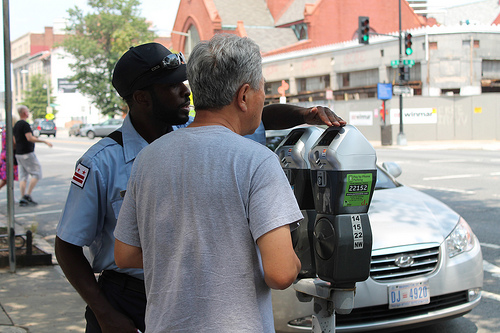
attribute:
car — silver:
[267, 128, 483, 331]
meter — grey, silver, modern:
[276, 125, 373, 290]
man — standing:
[115, 34, 302, 332]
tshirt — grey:
[114, 124, 299, 332]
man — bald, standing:
[13, 107, 52, 209]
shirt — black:
[13, 119, 36, 154]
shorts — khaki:
[16, 156, 44, 177]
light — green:
[362, 34, 368, 41]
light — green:
[405, 45, 411, 54]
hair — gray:
[186, 32, 263, 108]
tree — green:
[20, 78, 55, 131]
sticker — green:
[342, 173, 373, 212]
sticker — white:
[349, 216, 366, 250]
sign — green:
[390, 58, 413, 69]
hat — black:
[112, 38, 191, 90]